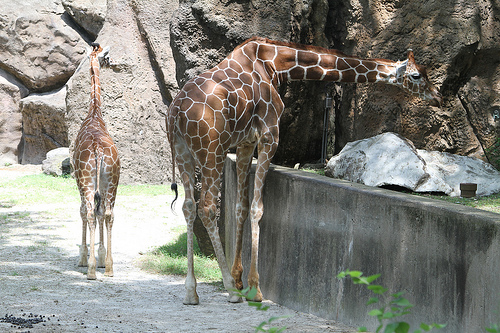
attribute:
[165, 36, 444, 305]
giraffe — mother, brown, adult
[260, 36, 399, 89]
neck — long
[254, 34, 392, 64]
mane — brown, short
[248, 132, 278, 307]
leg — long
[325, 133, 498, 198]
stone — white, large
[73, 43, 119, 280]
giraffe — baby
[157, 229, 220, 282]
grass — green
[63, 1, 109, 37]
rock — brown, large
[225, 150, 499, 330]
wall — low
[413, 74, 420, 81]
eye — large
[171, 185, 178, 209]
hair — black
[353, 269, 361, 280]
leaf — green